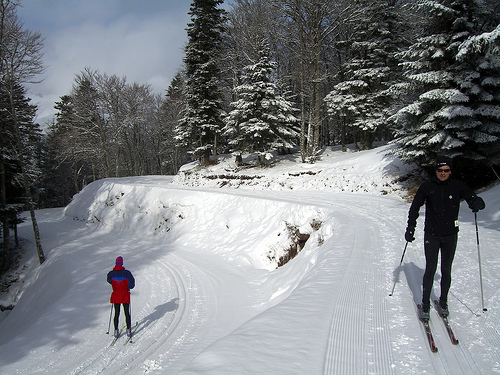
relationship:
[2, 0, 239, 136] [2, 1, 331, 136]
clouds are in sky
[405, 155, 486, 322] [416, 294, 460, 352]
man standing on skis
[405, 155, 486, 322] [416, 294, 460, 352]
man on skis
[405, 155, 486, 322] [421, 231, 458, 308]
man wearing pants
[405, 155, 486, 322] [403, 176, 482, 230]
man wearing a jacket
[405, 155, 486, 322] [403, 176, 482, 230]
man wearing jacket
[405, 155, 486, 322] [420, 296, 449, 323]
man wearing boots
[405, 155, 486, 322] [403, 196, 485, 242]
man wearing gloves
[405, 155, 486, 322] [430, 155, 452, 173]
man wearing a hat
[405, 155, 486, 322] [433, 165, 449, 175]
man wearing glasses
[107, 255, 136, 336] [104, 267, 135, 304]
person wearing coat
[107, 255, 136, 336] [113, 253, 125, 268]
person wearing a hat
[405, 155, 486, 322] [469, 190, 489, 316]
man holding ski pole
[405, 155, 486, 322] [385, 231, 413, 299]
man holding ski pole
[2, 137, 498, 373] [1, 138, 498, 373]
ground covered with snow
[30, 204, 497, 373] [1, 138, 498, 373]
tracks are on snow